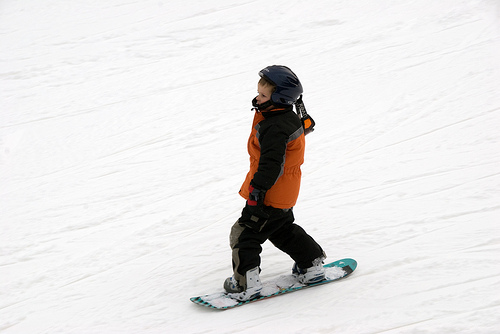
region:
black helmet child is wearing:
[260, 63, 304, 110]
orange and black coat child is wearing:
[225, 105, 308, 217]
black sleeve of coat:
[245, 123, 288, 190]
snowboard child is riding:
[187, 253, 364, 312]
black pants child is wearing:
[225, 204, 322, 275]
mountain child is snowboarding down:
[7, 8, 499, 313]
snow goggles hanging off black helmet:
[292, 95, 317, 137]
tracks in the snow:
[43, 23, 488, 318]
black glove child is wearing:
[243, 191, 262, 202]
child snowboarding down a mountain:
[168, 57, 360, 313]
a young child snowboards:
[122, 27, 384, 312]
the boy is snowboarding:
[144, 33, 424, 318]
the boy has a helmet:
[135, 2, 391, 294]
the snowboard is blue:
[144, 264, 494, 305]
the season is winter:
[101, 20, 436, 322]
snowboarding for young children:
[115, 36, 435, 317]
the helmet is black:
[164, 30, 479, 332]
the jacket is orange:
[106, 25, 418, 318]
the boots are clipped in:
[173, 45, 396, 327]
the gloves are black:
[131, 22, 411, 319]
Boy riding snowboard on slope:
[192, 62, 357, 317]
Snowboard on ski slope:
[184, 256, 365, 311]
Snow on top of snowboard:
[193, 264, 342, 311]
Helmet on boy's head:
[253, 63, 303, 110]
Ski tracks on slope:
[9, 14, 481, 77]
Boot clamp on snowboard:
[223, 264, 264, 301]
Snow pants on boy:
[230, 203, 325, 279]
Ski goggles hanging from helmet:
[298, 96, 316, 136]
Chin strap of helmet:
[246, 99, 274, 111]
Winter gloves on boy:
[247, 185, 269, 202]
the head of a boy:
[250, 59, 311, 126]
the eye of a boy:
[241, 78, 276, 111]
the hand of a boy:
[233, 172, 308, 239]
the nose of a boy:
[246, 88, 271, 110]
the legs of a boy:
[231, 186, 333, 293]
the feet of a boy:
[214, 220, 376, 307]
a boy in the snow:
[180, 28, 428, 325]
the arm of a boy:
[231, 125, 316, 214]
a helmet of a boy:
[187, 52, 407, 317]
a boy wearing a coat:
[214, 57, 357, 242]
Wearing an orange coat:
[233, 105, 313, 225]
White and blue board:
[181, 253, 364, 309]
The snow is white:
[37, 153, 127, 243]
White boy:
[240, 65, 275, 101]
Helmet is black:
[237, 55, 337, 120]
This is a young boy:
[190, 35, 345, 295]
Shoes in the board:
[195, 240, 330, 305]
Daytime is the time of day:
[5, 5, 485, 330]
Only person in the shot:
[155, 40, 360, 330]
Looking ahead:
[231, 53, 314, 130]